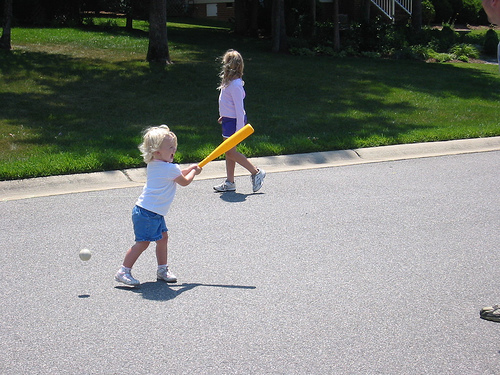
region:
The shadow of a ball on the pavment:
[66, 283, 96, 301]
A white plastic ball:
[62, 232, 110, 265]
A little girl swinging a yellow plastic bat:
[118, 107, 267, 269]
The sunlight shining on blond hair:
[133, 116, 193, 173]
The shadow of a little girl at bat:
[111, 266, 265, 320]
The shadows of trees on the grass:
[34, 52, 375, 135]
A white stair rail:
[372, 0, 432, 43]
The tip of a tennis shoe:
[473, 302, 497, 322]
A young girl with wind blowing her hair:
[205, 44, 267, 197]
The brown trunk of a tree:
[142, 9, 181, 66]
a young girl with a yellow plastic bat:
[62, 100, 263, 328]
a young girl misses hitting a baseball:
[52, 110, 279, 326]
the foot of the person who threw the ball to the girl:
[468, 287, 498, 336]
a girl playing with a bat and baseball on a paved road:
[3, 86, 314, 358]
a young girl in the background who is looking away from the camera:
[175, 36, 302, 221]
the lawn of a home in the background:
[3, 4, 488, 191]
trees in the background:
[79, 5, 496, 97]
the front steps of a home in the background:
[355, 1, 496, 81]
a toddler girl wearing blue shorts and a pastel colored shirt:
[110, 119, 212, 296]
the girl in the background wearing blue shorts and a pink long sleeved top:
[203, 37, 284, 209]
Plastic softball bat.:
[187, 123, 262, 176]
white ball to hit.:
[69, 236, 99, 266]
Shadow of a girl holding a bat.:
[119, 260, 259, 305]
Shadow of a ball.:
[63, 274, 98, 302]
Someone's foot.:
[470, 297, 499, 331]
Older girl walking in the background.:
[199, 34, 266, 199]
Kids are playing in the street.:
[20, 147, 490, 348]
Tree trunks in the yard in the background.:
[8, 0, 190, 91]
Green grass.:
[13, 30, 474, 139]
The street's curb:
[7, 122, 497, 210]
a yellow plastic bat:
[187, 118, 254, 182]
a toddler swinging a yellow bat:
[116, 109, 256, 294]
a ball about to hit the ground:
[71, 241, 95, 266]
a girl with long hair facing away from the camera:
[213, 47, 265, 199]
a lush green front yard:
[3, 6, 498, 160]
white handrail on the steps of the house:
[376, 1, 418, 23]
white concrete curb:
[3, 132, 498, 202]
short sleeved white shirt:
[136, 156, 186, 216]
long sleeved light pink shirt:
[214, 73, 247, 135]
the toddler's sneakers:
[105, 258, 178, 290]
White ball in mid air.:
[78, 244, 92, 262]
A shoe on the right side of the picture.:
[477, 301, 498, 321]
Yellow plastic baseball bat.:
[190, 120, 255, 172]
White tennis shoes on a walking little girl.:
[212, 166, 269, 192]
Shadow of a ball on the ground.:
[76, 293, 91, 300]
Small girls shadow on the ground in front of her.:
[109, 278, 256, 302]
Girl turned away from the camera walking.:
[210, 49, 268, 194]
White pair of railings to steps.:
[372, 0, 416, 23]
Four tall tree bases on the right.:
[265, 0, 344, 54]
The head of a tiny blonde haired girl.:
[135, 124, 180, 164]